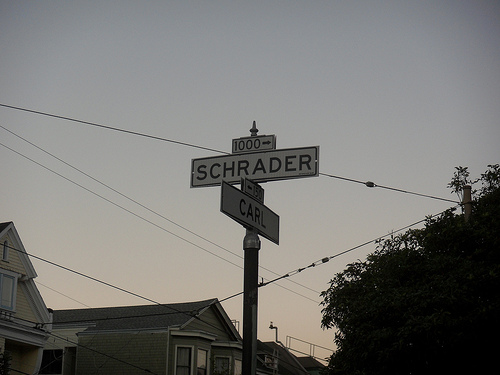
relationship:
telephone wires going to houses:
[2, 98, 459, 373] [0, 220, 324, 372]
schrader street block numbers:
[162, 140, 342, 247] [232, 136, 263, 151]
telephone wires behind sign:
[216, 204, 464, 304] [197, 150, 304, 197]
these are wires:
[62, 142, 111, 206] [142, 226, 197, 289]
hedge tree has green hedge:
[321, 164, 500, 374] [321, 164, 500, 374]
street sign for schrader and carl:
[170, 165, 301, 172] [134, 110, 341, 369]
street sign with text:
[218, 179, 280, 246] [233, 195, 269, 230]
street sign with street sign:
[188, 139, 323, 186] [196, 154, 314, 181]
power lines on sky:
[0, 99, 460, 308] [2, 0, 483, 340]